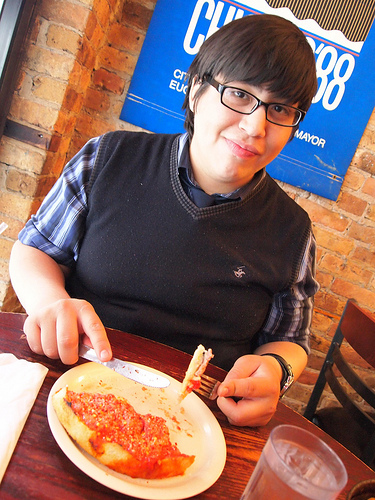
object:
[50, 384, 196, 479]
pizza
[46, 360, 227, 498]
plate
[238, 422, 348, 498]
cup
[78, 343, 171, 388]
knife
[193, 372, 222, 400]
fork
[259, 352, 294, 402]
watch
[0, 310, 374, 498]
table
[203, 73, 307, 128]
glasses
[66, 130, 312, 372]
vest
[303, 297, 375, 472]
chair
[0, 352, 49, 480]
napkin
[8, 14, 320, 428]
man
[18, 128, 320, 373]
shirt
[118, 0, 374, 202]
poster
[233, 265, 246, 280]
logo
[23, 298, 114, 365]
hands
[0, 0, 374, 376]
wall